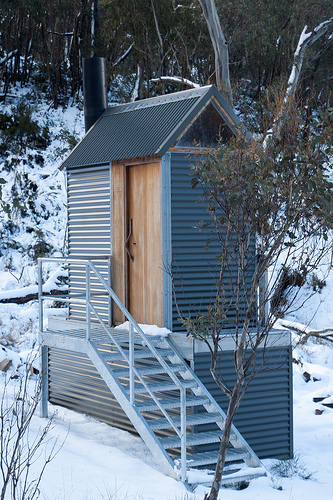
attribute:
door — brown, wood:
[126, 163, 166, 323]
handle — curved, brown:
[125, 219, 134, 265]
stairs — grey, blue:
[84, 332, 275, 491]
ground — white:
[3, 369, 332, 500]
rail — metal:
[36, 254, 187, 467]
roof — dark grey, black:
[55, 86, 214, 171]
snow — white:
[51, 410, 172, 500]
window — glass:
[173, 100, 248, 151]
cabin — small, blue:
[42, 85, 295, 444]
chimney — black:
[82, 52, 108, 131]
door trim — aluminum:
[123, 163, 127, 327]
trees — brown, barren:
[3, 0, 332, 110]